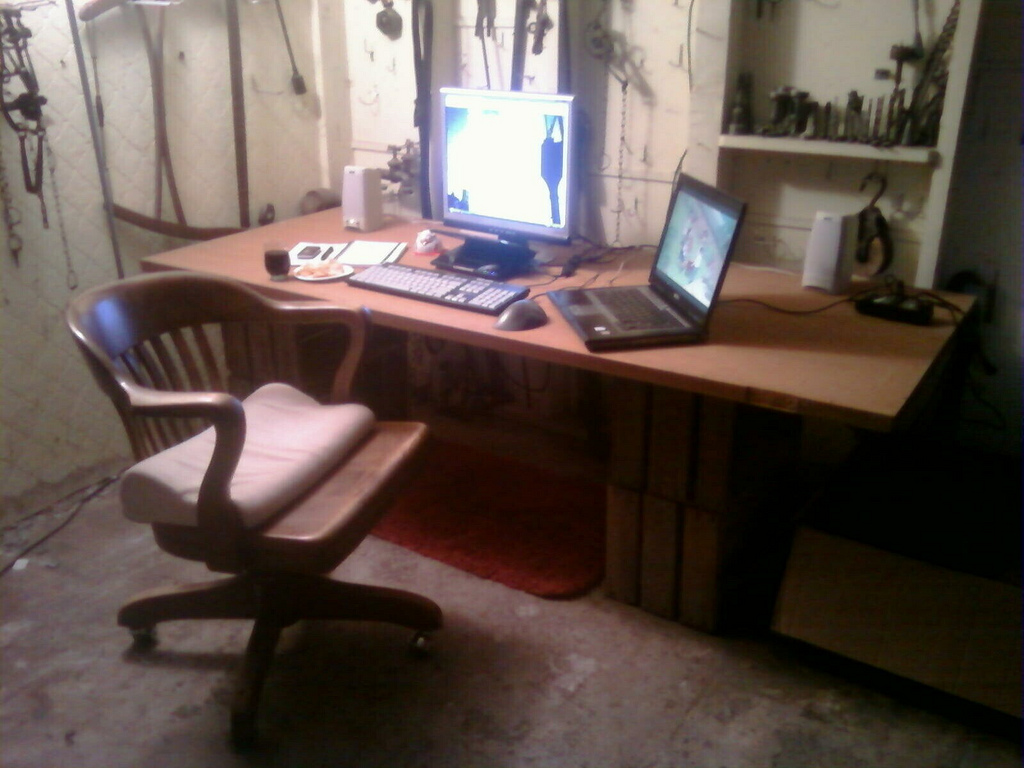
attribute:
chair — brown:
[36, 273, 501, 736]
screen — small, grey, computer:
[440, 93, 574, 249]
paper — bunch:
[295, 237, 412, 287]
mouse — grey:
[500, 294, 555, 349]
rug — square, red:
[321, 421, 615, 622]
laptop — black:
[541, 177, 753, 385]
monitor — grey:
[414, 97, 603, 251]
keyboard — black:
[353, 257, 541, 318]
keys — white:
[377, 266, 427, 293]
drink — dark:
[273, 251, 280, 264]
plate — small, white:
[284, 257, 358, 281]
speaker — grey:
[340, 162, 384, 236]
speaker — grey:
[805, 214, 858, 297]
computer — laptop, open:
[552, 175, 756, 376]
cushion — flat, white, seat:
[120, 376, 388, 543]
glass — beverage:
[256, 238, 298, 278]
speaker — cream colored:
[807, 199, 860, 295]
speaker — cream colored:
[329, 153, 388, 231]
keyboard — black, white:
[353, 251, 526, 312]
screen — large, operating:
[426, 103, 584, 235]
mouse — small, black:
[502, 302, 541, 341]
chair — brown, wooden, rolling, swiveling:
[61, 261, 455, 752]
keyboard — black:
[345, 259, 533, 327]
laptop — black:
[539, 179, 740, 370]